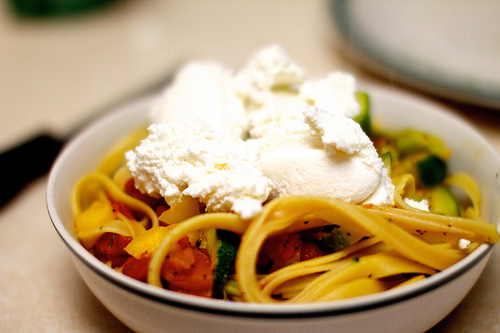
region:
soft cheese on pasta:
[128, 64, 391, 226]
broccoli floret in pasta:
[201, 233, 251, 316]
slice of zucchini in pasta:
[407, 152, 462, 232]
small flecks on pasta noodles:
[362, 206, 486, 262]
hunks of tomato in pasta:
[89, 214, 219, 296]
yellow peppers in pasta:
[122, 220, 192, 265]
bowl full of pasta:
[35, 57, 490, 321]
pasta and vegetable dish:
[90, 196, 461, 290]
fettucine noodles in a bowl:
[249, 202, 486, 292]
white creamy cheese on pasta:
[160, 85, 364, 250]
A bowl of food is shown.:
[49, 60, 497, 325]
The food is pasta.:
[86, 176, 441, 299]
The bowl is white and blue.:
[55, 70, 496, 332]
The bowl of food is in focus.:
[73, 52, 494, 329]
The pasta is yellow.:
[244, 189, 467, 297]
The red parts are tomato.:
[161, 245, 217, 292]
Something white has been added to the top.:
[160, 67, 371, 197]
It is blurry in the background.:
[8, 5, 148, 159]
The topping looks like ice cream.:
[139, 66, 379, 216]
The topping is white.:
[136, 71, 398, 216]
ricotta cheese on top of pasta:
[162, 77, 347, 187]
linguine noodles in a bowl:
[252, 205, 438, 284]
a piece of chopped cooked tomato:
[176, 242, 209, 287]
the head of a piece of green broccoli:
[215, 235, 231, 285]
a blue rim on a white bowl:
[75, 254, 132, 297]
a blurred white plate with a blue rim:
[345, 2, 496, 104]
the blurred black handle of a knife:
[11, 133, 46, 187]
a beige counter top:
[5, 260, 68, 327]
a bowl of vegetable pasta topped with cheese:
[45, 40, 489, 331]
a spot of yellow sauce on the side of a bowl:
[458, 131, 483, 161]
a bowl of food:
[40, 40, 499, 330]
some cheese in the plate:
[120, 45, 396, 211]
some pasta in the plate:
[78, 192, 498, 297]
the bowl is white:
[40, 49, 499, 331]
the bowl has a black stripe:
[43, 62, 498, 331]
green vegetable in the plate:
[204, 236, 251, 297]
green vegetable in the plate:
[417, 150, 448, 188]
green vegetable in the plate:
[323, 230, 352, 252]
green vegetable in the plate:
[352, 90, 384, 127]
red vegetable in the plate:
[160, 228, 216, 296]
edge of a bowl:
[35, 166, 70, 233]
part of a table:
[56, 294, 76, 315]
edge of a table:
[27, 206, 34, 222]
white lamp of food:
[271, 147, 283, 154]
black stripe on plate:
[387, 289, 409, 297]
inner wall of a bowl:
[65, 189, 67, 201]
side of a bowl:
[358, 312, 377, 320]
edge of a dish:
[90, 252, 98, 262]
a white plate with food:
[378, 303, 397, 326]